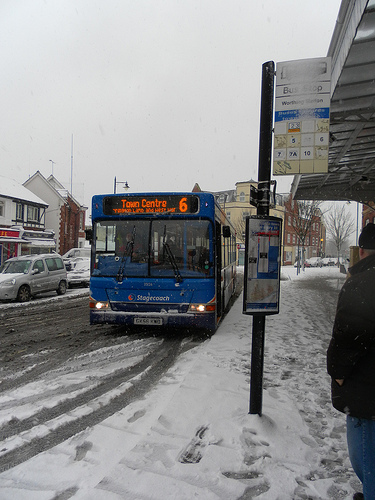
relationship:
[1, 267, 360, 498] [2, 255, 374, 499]
snow on ground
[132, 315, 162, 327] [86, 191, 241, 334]
license plate on bus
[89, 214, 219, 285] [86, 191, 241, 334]
windshield on bus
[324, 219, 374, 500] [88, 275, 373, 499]
person on sidewalk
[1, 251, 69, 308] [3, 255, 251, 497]
vehicles on side of road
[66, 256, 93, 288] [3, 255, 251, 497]
vehicles on side of road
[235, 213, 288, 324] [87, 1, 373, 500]
sign at stop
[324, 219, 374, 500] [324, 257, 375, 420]
person in jacket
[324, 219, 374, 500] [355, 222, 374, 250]
person in hat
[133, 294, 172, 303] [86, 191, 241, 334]
logo on bus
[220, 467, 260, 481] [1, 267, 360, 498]
footprint in snow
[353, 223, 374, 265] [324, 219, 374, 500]
head of person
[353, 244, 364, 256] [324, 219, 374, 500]
ear of person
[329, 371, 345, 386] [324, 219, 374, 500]
hand of person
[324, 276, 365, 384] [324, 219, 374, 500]
arm of person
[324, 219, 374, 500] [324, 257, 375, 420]
person wearing jacket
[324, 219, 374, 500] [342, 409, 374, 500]
person wearing pants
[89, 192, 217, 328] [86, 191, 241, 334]
front of bus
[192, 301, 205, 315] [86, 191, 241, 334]
headlights on bus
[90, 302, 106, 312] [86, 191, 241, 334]
headlights on bus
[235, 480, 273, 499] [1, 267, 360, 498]
footprint in snow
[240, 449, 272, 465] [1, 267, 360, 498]
footprint in snow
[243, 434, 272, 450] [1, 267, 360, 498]
footprint in snow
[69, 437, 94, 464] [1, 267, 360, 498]
footprint in snow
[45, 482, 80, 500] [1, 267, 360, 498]
footprint in snow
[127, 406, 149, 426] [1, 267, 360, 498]
footprint in snow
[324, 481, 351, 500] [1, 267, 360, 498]
footprint in snow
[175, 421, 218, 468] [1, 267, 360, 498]
tracks in snow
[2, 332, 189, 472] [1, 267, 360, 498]
tracks in snow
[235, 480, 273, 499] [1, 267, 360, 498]
footprint on snow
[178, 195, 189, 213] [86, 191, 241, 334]
number on bus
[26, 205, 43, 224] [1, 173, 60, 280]
windows on building